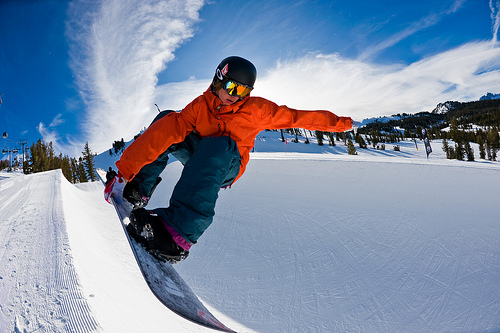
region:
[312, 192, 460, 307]
The ground is snow covered.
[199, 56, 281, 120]
He is wearing a helmet.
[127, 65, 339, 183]
He has an orange jacket on.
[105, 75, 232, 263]
He has blue pants.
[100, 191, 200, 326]
His snow board is black.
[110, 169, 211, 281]
His boots are black.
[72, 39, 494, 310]
He is boarding in the half pipe.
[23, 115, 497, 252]
He is doing a trick.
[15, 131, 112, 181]
The trees are leafy.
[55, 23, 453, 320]
The sun is shining.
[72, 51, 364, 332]
Snowboarder in the air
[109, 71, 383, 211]
Orange jacket worn by snowboarder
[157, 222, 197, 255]
Pink trim on bottom of pants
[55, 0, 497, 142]
Large white wispy cloud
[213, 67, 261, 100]
Goggles worn by snowboarder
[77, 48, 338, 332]
a boy on a snowboard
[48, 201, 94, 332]
Lines in the snow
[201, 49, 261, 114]
Black hat on snowboarder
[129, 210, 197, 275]
Black boots on snowbarder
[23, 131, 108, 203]
a patch of tall trees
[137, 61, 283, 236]
this is a boy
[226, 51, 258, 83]
this is a helmet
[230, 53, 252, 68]
the helmet is black in color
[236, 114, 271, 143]
this is a jacket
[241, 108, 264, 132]
the jacket is orange in color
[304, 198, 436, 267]
this is the snow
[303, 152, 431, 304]
the snow is white in color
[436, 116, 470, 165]
this is a tree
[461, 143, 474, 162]
the leaves are green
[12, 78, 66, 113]
this is the sky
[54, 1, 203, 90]
white cloud is in blue sky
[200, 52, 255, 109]
black helmet is on person's head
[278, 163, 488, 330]
white snow is covering slope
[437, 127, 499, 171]
green trees are in white snow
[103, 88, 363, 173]
man is wearing orange jacket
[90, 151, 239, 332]
man has black snowboard attached to his feet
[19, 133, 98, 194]
green trees are in white snow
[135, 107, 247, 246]
snowboarding man wearing blue pants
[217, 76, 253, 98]
snowboarding man is wearing yellow goggles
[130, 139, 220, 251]
blue pants have purple bands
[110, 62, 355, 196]
a boy wearing a orange jacket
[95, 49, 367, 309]
a boy snow boarding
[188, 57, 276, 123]
a boy wearing goggles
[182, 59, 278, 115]
a boy wearing a black helmet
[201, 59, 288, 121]
a boy wearing a helmet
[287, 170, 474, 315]
ground covered with snow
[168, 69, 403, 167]
a boy with his arm stretched out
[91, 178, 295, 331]
a long snow board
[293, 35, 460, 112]
white clouds in a blue sky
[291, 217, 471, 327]
tracks in the snow